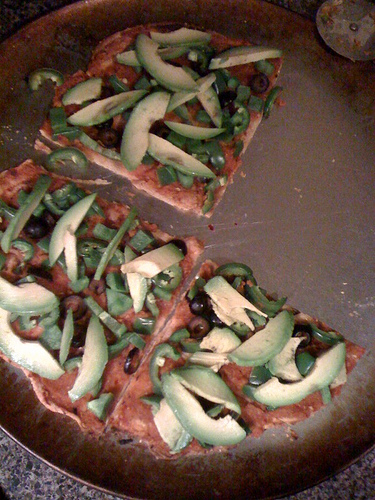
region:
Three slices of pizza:
[12, 11, 349, 450]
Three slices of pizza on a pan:
[8, 15, 338, 472]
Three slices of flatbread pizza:
[15, 11, 363, 464]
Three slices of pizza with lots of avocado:
[2, 0, 342, 441]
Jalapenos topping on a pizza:
[19, 50, 109, 263]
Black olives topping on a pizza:
[14, 192, 104, 322]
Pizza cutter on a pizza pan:
[250, 3, 370, 78]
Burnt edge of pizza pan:
[0, 3, 335, 99]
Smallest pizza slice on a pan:
[117, 259, 360, 458]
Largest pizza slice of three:
[4, 142, 195, 444]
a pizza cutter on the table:
[316, 1, 374, 61]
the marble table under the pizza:
[6, 462, 44, 494]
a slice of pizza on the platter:
[36, 19, 284, 215]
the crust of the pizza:
[39, 428, 372, 496]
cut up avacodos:
[158, 368, 244, 441]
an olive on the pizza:
[184, 318, 211, 334]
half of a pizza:
[1, 159, 373, 487]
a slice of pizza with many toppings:
[96, 257, 374, 490]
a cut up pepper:
[27, 68, 65, 89]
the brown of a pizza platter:
[288, 133, 369, 296]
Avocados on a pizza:
[140, 275, 345, 450]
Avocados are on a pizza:
[148, 272, 346, 449]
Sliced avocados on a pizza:
[155, 274, 344, 451]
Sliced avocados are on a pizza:
[155, 272, 347, 450]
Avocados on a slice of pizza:
[148, 274, 349, 450]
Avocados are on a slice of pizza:
[154, 272, 349, 456]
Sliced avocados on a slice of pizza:
[148, 274, 346, 450]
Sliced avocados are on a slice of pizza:
[141, 272, 346, 452]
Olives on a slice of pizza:
[184, 290, 319, 352]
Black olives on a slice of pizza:
[185, 291, 328, 354]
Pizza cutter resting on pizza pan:
[315, 0, 372, 60]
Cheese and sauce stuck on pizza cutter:
[316, 1, 367, 51]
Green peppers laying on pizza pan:
[27, 67, 87, 168]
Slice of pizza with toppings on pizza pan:
[37, 18, 283, 216]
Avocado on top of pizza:
[161, 363, 247, 446]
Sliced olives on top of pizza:
[189, 293, 225, 337]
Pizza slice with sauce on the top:
[92, 258, 373, 495]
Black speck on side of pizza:
[119, 437, 135, 445]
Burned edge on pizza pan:
[6, 1, 315, 67]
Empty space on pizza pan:
[229, 62, 374, 344]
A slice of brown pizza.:
[90, 252, 357, 474]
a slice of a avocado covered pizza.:
[0, 190, 214, 436]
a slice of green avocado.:
[222, 296, 297, 367]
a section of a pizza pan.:
[283, 245, 317, 262]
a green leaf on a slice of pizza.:
[284, 327, 345, 384]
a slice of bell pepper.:
[144, 329, 188, 397]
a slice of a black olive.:
[118, 340, 157, 381]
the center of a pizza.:
[182, 232, 219, 283]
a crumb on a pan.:
[333, 276, 351, 286]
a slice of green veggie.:
[61, 308, 120, 414]